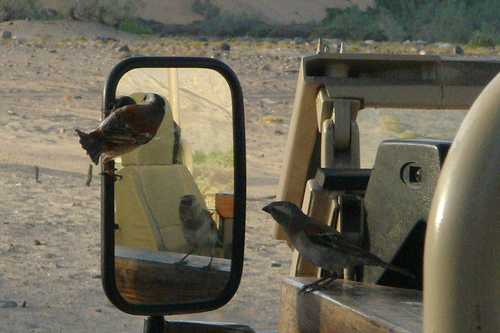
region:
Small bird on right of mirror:
[245, 166, 405, 296]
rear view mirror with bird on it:
[85, 35, 261, 315]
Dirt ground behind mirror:
[5, 25, 457, 324]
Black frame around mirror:
[87, 44, 259, 309]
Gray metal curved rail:
[393, 46, 498, 306]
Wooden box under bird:
[270, 271, 396, 331]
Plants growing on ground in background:
[8, 5, 484, 59]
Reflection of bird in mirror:
[160, 184, 227, 249]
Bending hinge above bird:
[291, 80, 371, 165]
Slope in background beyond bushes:
[10, 3, 480, 55]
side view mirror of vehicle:
[101, 57, 244, 316]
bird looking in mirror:
[77, 89, 167, 162]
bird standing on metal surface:
[260, 199, 416, 294]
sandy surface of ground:
[4, 19, 496, 327]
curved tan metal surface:
[423, 73, 495, 328]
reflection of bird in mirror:
[175, 190, 221, 272]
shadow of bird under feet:
[290, 282, 330, 329]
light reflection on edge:
[382, 137, 440, 151]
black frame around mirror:
[99, 55, 246, 314]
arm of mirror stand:
[137, 314, 253, 331]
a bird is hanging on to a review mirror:
[73, 88, 177, 166]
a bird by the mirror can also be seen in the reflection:
[175, 188, 418, 303]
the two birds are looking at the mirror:
[72, 85, 423, 309]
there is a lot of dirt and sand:
[1, 13, 499, 331]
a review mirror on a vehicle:
[76, 46, 264, 329]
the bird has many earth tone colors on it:
[259, 195, 421, 306]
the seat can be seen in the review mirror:
[111, 90, 223, 259]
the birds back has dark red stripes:
[70, 85, 168, 165]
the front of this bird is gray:
[168, 190, 227, 275]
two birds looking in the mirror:
[75, 49, 419, 297]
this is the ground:
[21, 66, 52, 159]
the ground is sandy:
[15, 200, 63, 248]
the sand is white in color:
[13, 159, 55, 282]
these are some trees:
[301, 9, 499, 48]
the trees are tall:
[344, 5, 490, 34]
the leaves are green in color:
[341, 6, 408, 41]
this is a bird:
[76, 90, 171, 160]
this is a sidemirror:
[98, 58, 243, 310]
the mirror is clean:
[174, 75, 209, 155]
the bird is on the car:
[259, 184, 395, 292]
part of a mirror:
[156, 173, 188, 212]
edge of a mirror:
[228, 193, 273, 264]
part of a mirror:
[181, 238, 228, 298]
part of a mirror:
[155, 178, 194, 230]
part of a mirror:
[195, 215, 226, 256]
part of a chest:
[299, 236, 319, 263]